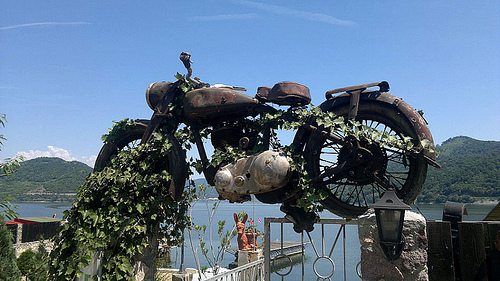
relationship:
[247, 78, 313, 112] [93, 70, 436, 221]
seat on bike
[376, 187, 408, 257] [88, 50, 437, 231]
lamp under bike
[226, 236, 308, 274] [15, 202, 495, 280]
dock on lake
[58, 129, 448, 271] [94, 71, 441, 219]
ivy grows on motorcycle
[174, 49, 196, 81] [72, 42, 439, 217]
handles on motorcycle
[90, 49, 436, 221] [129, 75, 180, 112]
bike has headlight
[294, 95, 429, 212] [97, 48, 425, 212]
wheel on motorcycle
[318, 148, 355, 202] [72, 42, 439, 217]
spokes on motorcycle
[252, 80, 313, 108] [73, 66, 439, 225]
seat on motorcycle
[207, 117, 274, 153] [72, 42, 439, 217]
gears on motorcycle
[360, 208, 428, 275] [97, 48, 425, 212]
stone fence by motorcycle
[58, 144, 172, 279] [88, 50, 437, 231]
leaves growing on bike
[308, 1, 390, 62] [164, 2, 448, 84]
clouds in sky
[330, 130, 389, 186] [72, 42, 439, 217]
wheel of motorcycle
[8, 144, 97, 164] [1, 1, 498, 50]
clouds in sky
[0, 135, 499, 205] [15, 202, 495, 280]
hills bordering lake